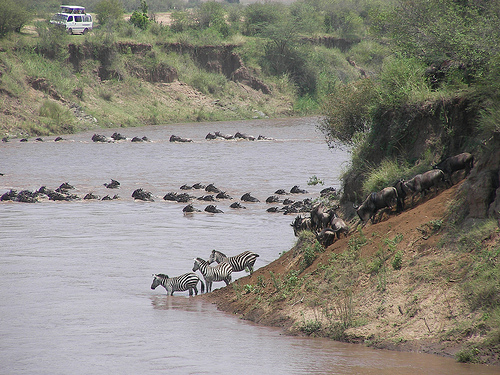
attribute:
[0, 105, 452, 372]
river — muddy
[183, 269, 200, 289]
zebra — part , xrnra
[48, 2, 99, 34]
van — white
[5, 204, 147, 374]
water — calm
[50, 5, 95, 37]
vehicles — parked, distant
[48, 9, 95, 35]
van — white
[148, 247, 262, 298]
zebras — three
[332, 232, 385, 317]
ground — part 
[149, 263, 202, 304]
zebra — fat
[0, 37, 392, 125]
cliff — dirt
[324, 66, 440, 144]
leaves — green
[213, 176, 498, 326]
dirt — brown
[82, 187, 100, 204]
wild beast — swimming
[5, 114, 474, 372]
hole — watering 